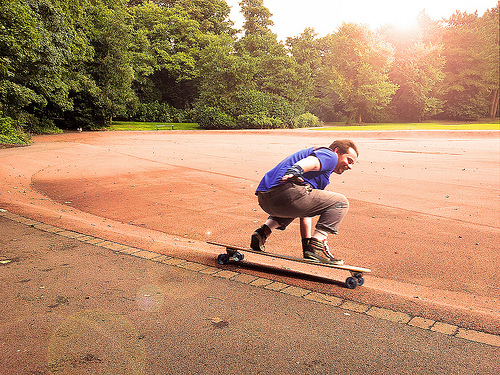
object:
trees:
[244, 0, 305, 124]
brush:
[128, 97, 192, 123]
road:
[0, 128, 498, 337]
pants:
[257, 185, 349, 236]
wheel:
[233, 252, 244, 262]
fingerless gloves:
[284, 164, 305, 182]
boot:
[250, 221, 271, 251]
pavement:
[20, 269, 258, 359]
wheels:
[216, 253, 229, 263]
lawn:
[110, 122, 499, 131]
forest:
[1, 0, 498, 145]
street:
[2, 212, 500, 374]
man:
[250, 139, 358, 264]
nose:
[347, 163, 352, 169]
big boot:
[301, 238, 345, 267]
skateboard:
[205, 241, 372, 289]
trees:
[71, 0, 154, 123]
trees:
[3, 0, 96, 141]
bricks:
[0, 207, 497, 371]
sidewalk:
[0, 214, 500, 375]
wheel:
[346, 277, 356, 288]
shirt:
[255, 146, 338, 194]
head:
[329, 139, 359, 175]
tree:
[199, 3, 298, 125]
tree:
[275, 25, 326, 126]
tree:
[324, 22, 397, 122]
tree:
[395, 24, 451, 120]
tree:
[441, 4, 498, 121]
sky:
[226, 3, 496, 54]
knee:
[323, 192, 349, 220]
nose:
[355, 267, 371, 274]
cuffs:
[313, 148, 330, 172]